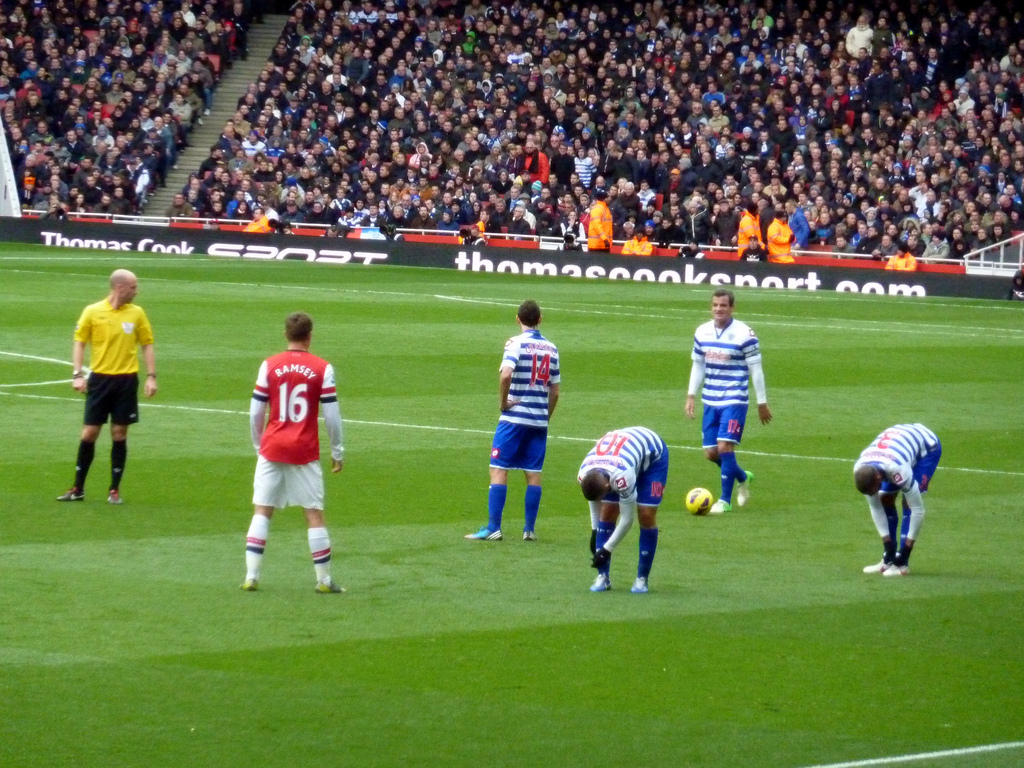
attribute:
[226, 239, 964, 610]
men — soccer playing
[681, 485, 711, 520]
soccerball — yellow, black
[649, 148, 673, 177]
person — seated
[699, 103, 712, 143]
person — seated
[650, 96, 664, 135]
person — seated